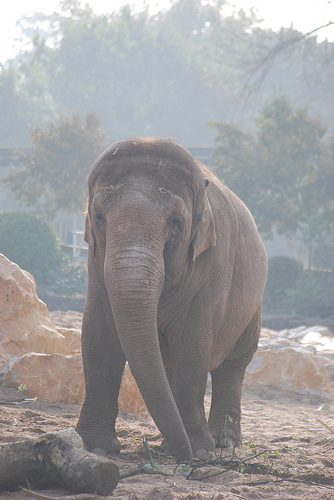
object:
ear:
[191, 178, 217, 262]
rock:
[249, 340, 334, 401]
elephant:
[74, 137, 266, 462]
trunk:
[102, 217, 193, 464]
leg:
[74, 238, 127, 457]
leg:
[167, 334, 215, 458]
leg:
[208, 307, 262, 448]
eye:
[96, 214, 102, 220]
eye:
[171, 216, 178, 224]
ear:
[83, 212, 95, 257]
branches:
[119, 415, 275, 483]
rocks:
[47, 307, 83, 330]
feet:
[73, 428, 243, 457]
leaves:
[243, 442, 256, 454]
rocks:
[0, 250, 81, 405]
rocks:
[274, 324, 333, 361]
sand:
[285, 398, 330, 436]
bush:
[295, 273, 333, 321]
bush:
[281, 270, 306, 303]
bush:
[0, 210, 44, 250]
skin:
[209, 256, 252, 313]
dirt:
[0, 393, 334, 498]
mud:
[302, 425, 331, 444]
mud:
[193, 486, 230, 498]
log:
[0, 426, 120, 496]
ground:
[9, 384, 332, 498]